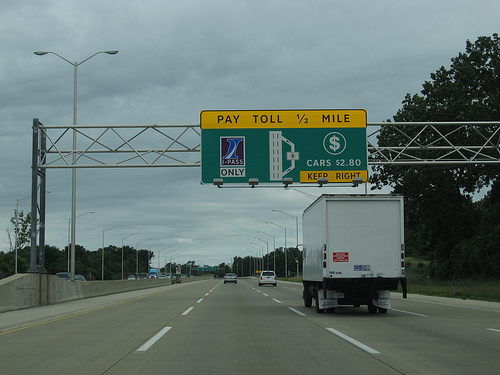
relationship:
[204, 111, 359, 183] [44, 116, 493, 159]
sign on pole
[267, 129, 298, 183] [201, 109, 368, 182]
white image on sign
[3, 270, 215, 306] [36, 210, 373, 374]
side of road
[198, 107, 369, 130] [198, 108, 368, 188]
yellow bar on sign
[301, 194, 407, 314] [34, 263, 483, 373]
truck in street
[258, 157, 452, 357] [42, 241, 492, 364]
truck on road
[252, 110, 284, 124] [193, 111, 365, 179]
writing on sign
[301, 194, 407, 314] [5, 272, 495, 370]
truck on road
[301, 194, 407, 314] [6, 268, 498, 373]
truck on freeway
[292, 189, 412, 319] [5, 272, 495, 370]
truck on road